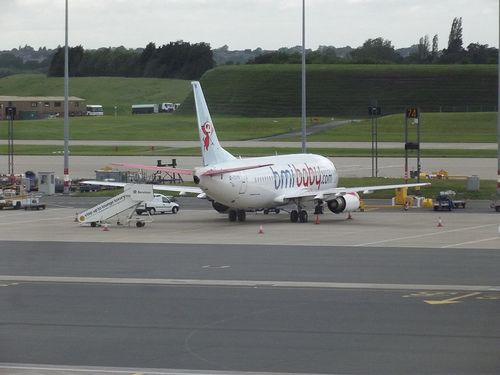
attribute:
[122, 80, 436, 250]
airplane — white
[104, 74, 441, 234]
airplane — passenger, white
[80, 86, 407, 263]
airplane — large, white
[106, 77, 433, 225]
plane — large, white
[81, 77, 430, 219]
airplane — large, white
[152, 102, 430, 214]
plane — white